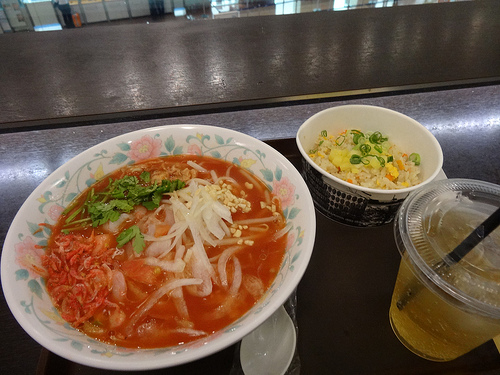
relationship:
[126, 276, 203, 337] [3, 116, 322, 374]
onion in dish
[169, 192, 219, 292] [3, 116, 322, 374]
onion in dish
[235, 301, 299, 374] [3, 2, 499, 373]
spoon on table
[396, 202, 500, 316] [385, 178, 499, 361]
straw in cup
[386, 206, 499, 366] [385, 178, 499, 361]
juice in cup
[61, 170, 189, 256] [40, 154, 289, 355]
coriander in soup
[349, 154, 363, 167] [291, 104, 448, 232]
pepper in bowl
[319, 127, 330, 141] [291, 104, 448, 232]
pepper in bowl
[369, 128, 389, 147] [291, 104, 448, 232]
pepper in bowl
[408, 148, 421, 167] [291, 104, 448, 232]
pepper in bowl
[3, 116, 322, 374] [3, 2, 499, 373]
dish on table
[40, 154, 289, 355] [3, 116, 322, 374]
soup in dish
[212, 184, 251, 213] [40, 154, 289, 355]
cheese in soup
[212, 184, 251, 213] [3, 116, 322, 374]
cheese in dish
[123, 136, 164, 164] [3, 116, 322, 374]
flower on dish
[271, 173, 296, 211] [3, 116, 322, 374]
flower on dish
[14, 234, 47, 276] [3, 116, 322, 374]
flower on dish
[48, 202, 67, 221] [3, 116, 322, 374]
flower on dish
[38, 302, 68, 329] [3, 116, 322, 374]
flower on dish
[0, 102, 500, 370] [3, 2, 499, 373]
meal on top of table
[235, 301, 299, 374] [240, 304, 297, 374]
spoon has spoon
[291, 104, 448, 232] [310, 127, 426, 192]
bowl contains rice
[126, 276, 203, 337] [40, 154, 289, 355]
onion in soup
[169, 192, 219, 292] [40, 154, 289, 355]
onion in soup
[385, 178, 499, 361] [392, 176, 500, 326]
cup has lid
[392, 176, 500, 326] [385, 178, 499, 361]
lid on top of cup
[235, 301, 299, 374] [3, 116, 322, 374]
spoon under dish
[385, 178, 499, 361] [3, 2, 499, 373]
cup on table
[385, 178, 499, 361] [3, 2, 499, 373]
cup sitting on table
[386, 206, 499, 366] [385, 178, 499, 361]
juice inside cup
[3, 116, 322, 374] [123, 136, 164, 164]
dish has flower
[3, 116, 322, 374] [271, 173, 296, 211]
dish has flower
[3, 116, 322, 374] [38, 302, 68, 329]
dish has flower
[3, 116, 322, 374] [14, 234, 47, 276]
dish has flower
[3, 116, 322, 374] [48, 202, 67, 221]
dish has flower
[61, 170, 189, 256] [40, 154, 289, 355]
coriander on top of soup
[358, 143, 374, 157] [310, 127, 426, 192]
scallion on top of rice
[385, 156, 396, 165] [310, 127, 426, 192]
scallion on top of rice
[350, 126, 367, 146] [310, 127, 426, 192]
scallion on top of rice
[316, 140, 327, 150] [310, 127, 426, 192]
scallion on top of rice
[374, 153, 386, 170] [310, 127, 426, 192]
scallion on top of rice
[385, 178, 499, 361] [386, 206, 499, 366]
cup contains juice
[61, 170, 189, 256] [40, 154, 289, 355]
coriander on soup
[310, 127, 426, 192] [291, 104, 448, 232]
rice in bowl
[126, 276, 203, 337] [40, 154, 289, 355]
onion on top of soup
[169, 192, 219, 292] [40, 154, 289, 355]
onion on top of soup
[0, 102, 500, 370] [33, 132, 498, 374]
meal on tray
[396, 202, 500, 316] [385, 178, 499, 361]
straw inside cup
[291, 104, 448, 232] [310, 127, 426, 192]
bowl holds rice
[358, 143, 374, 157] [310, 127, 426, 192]
scallion in rice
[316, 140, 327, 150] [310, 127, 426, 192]
scallion in rice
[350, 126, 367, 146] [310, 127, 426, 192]
scallion in rice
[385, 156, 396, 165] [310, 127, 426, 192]
scallion in rice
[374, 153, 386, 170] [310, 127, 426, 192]
scallion in rice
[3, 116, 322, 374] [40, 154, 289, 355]
dish holds soup